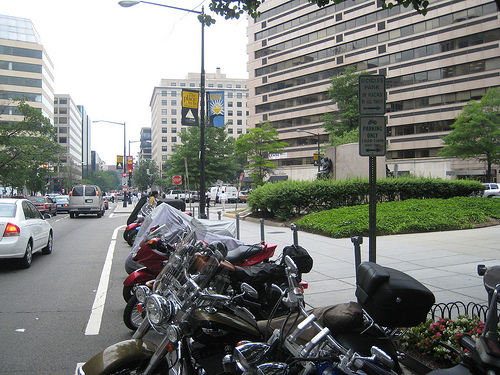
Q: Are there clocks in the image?
A: No, there are no clocks.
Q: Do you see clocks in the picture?
A: No, there are no clocks.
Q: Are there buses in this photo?
A: No, there are no buses.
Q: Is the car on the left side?
A: Yes, the car is on the left of the image.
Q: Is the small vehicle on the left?
A: Yes, the car is on the left of the image.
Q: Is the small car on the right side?
A: No, the car is on the left of the image.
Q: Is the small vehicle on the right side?
A: No, the car is on the left of the image.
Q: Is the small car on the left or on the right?
A: The car is on the left of the image.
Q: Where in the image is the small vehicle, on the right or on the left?
A: The car is on the left of the image.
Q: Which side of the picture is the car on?
A: The car is on the left of the image.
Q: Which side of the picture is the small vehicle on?
A: The car is on the left of the image.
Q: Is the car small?
A: Yes, the car is small.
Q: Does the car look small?
A: Yes, the car is small.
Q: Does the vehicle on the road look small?
A: Yes, the car is small.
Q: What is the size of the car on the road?
A: The car is small.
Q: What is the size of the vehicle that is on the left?
A: The car is small.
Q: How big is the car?
A: The car is small.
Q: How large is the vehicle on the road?
A: The car is small.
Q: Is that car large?
A: No, the car is small.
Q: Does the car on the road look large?
A: No, the car is small.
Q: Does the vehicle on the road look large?
A: No, the car is small.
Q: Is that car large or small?
A: The car is small.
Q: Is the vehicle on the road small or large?
A: The car is small.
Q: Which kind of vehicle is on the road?
A: The vehicle is a car.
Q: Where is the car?
A: The car is on the road.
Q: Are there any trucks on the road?
A: No, there is a car on the road.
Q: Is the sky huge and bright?
A: Yes, the sky is huge and bright.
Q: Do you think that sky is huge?
A: Yes, the sky is huge.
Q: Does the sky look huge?
A: Yes, the sky is huge.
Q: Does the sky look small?
A: No, the sky is huge.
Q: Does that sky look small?
A: No, the sky is huge.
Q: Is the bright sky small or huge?
A: The sky is huge.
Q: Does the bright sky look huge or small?
A: The sky is huge.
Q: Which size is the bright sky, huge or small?
A: The sky is huge.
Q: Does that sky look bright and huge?
A: Yes, the sky is bright and huge.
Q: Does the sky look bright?
A: Yes, the sky is bright.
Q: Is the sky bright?
A: Yes, the sky is bright.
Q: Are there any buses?
A: No, there are no buses.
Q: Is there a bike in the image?
A: Yes, there are bikes.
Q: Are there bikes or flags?
A: Yes, there are bikes.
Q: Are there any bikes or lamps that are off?
A: Yes, the bikes are off.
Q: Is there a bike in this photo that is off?
A: Yes, there are bikes that are off.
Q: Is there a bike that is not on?
A: Yes, there are bikes that are off.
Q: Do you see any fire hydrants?
A: No, there are no fire hydrants.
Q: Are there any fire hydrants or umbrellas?
A: No, there are no fire hydrants or umbrellas.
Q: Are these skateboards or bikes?
A: These are bikes.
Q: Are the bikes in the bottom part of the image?
A: Yes, the bikes are in the bottom of the image.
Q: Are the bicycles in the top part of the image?
A: No, the bicycles are in the bottom of the image.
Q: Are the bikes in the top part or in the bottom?
A: The bikes are in the bottom of the image.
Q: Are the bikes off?
A: Yes, the bikes are off.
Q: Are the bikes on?
A: No, the bikes are off.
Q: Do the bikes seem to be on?
A: No, the bikes are off.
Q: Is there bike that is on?
A: No, there are bikes but they are off.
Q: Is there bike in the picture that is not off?
A: No, there are bikes but they are off.